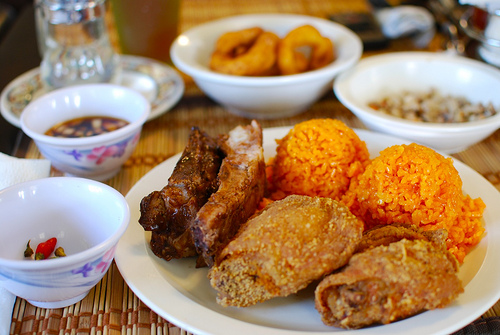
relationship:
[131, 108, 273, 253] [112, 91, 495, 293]
ribs on plate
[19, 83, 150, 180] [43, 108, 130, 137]
bowl of dark sauce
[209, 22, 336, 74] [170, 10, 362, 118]
onion rings in bowl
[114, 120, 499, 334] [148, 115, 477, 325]
plate of food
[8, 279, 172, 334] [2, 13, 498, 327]
placemat under food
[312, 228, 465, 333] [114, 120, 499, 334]
egg roll on plate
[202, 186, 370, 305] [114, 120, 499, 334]
egg roll on plate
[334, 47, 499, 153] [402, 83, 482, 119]
bowl with food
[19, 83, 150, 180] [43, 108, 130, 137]
bowl with dark sauce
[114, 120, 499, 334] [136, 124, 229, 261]
plate of food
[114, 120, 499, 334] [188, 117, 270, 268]
plate of food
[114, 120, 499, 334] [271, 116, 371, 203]
plate of food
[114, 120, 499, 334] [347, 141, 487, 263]
plate of food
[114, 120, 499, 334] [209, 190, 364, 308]
plate of food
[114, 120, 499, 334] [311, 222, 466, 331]
plate of food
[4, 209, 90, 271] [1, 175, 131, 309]
peppers in bowl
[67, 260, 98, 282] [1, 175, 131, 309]
flower on bowl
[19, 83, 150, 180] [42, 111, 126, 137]
bowl with sauce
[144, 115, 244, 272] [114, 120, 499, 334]
meat with plate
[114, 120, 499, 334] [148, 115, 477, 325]
plate with food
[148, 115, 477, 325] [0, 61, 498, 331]
food on a table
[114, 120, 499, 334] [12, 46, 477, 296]
plate on a table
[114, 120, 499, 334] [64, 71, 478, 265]
plate on a table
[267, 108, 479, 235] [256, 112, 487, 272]
stacks of rice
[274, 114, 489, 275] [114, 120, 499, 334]
rice on a plate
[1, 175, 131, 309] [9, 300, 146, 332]
bowl on a table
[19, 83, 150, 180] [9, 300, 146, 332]
bowl on a table